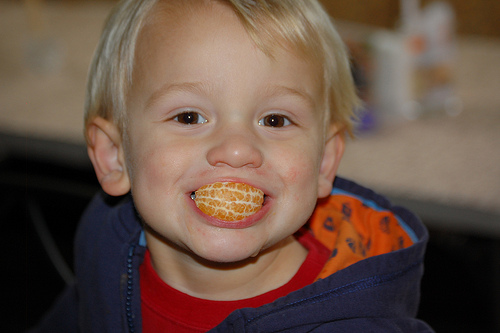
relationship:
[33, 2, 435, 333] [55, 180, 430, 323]
boy wearing hoodie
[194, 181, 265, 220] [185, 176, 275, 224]
fruit in mouth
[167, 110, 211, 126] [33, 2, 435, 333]
eye on boy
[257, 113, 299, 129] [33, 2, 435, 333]
eye on boy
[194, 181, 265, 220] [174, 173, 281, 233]
fruit in boy's mouth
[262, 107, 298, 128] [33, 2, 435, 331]
eye on boy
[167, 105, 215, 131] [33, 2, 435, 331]
eye on boy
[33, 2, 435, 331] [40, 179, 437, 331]
boy wearing a sweatshirt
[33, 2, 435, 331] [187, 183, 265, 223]
boy eating an orange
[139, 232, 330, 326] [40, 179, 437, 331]
red shirt under sweatshirt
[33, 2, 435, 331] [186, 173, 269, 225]
boy eating fruit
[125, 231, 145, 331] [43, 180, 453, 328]
zipper on hoodie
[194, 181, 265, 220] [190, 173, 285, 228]
fruit in mouth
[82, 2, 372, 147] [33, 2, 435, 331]
hair on boy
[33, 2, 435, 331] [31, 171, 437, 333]
boy wearing blue hoodie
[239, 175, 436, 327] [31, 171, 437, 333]
hood on blue hoodie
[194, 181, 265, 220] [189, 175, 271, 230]
fruit in mouth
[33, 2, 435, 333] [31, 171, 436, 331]
boy in blue hoodie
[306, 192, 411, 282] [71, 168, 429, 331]
inseam of hoodie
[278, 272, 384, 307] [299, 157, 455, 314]
stitching of hoodie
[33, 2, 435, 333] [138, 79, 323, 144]
boy has eyes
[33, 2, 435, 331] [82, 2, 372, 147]
boy has hair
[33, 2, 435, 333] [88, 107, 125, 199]
boy has left ear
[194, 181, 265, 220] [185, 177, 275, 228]
fruit in boy's mouth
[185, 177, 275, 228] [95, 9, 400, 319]
boy's mouth of boy